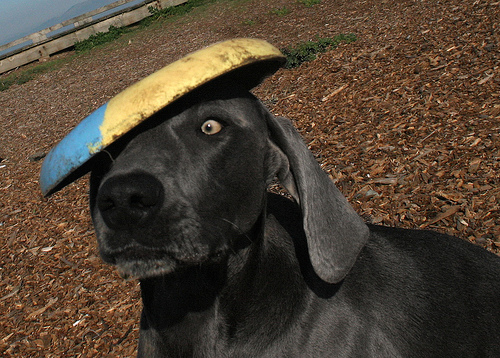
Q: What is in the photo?
A: A dog.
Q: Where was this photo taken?
A: Outdooors.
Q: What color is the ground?
A: Brown.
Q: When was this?
A: Daytime.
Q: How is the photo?
A: Clear.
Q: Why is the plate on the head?
A: It is playing.